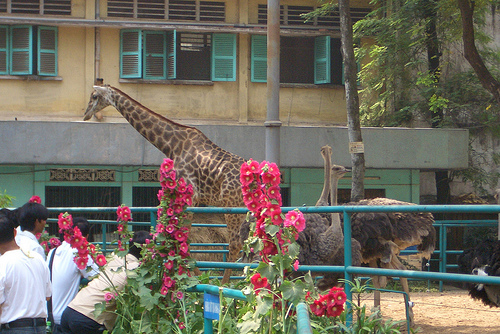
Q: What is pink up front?
A: The flowers.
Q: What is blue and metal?
A: The fence.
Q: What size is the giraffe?
A: Very tall.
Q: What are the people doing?
A: Watching.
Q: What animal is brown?
A: Giraffe.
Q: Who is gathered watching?
A: Group of men.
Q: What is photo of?
A: Animals in zoo.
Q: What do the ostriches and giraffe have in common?
A: Long Necks.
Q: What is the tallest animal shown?
A: Giraffe.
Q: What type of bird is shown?
A: Ostriches.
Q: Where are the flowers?
A: In front of the fence.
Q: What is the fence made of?
A: Metal.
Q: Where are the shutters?
A: On the windows of the building.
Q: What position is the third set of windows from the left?
A: Open.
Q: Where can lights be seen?
A: Through the open shutters.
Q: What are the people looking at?
A: The animals.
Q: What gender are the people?
A: Male.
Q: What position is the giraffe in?
A: Standing.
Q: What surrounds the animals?
A: A blue railing.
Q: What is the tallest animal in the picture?
A: A giraffe.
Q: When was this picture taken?
A: During the day.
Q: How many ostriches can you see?
A: Two.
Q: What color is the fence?
A: Blue.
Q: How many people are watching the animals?
A: Four.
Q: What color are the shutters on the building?
A: Teal.